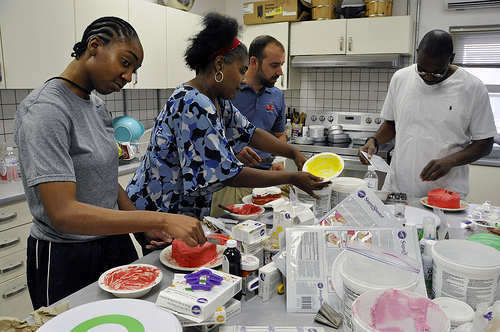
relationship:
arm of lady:
[25, 100, 206, 249] [26, 16, 208, 283]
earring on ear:
[213, 70, 225, 82] [214, 53, 223, 76]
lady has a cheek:
[26, 16, 208, 283] [92, 50, 117, 86]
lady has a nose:
[26, 16, 208, 283] [122, 67, 136, 84]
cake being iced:
[170, 236, 219, 268] [200, 229, 229, 247]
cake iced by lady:
[170, 236, 219, 268] [26, 16, 208, 283]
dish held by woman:
[302, 150, 346, 187] [134, 13, 332, 216]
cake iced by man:
[250, 188, 284, 207] [227, 34, 289, 222]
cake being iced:
[250, 188, 284, 207] [238, 145, 287, 166]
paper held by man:
[357, 147, 393, 178] [363, 26, 496, 205]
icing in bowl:
[308, 157, 341, 176] [302, 150, 346, 187]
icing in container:
[109, 269, 155, 286] [102, 262, 161, 294]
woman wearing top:
[134, 13, 332, 216] [133, 84, 254, 220]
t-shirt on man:
[370, 65, 499, 195] [363, 26, 496, 205]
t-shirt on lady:
[18, 80, 131, 239] [26, 16, 208, 283]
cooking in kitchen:
[133, 159, 494, 327] [2, 4, 500, 330]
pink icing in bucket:
[370, 294, 434, 329] [349, 286, 450, 330]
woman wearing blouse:
[134, 13, 332, 216] [133, 84, 254, 220]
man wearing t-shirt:
[363, 26, 496, 205] [370, 65, 499, 195]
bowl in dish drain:
[114, 113, 143, 142] [115, 132, 155, 162]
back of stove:
[304, 108, 399, 139] [297, 133, 390, 156]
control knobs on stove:
[308, 114, 382, 126] [297, 133, 390, 156]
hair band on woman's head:
[205, 35, 242, 57] [190, 15, 250, 98]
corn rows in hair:
[89, 17, 131, 40] [72, 14, 134, 56]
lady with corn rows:
[26, 16, 208, 283] [89, 17, 131, 40]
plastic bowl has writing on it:
[431, 238, 499, 298] [436, 270, 498, 299]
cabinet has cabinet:
[288, 18, 416, 56] [288, 18, 416, 56]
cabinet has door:
[288, 18, 416, 56] [290, 20, 348, 55]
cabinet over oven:
[288, 18, 416, 56] [294, 107, 394, 193]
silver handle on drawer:
[1, 209, 17, 221] [1, 200, 42, 225]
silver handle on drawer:
[2, 238, 19, 249] [1, 227, 38, 253]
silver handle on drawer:
[1, 262, 25, 274] [2, 248, 38, 277]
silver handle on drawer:
[4, 284, 30, 297] [0, 271, 58, 330]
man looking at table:
[363, 26, 496, 205] [45, 194, 498, 330]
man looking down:
[363, 26, 496, 205] [362, 151, 472, 205]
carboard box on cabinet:
[243, 2, 316, 23] [238, 22, 304, 95]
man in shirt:
[227, 34, 289, 222] [228, 79, 286, 160]